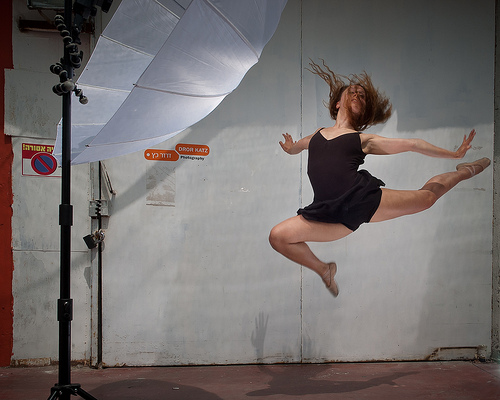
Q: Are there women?
A: Yes, there is a woman.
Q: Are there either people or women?
A: Yes, there is a woman.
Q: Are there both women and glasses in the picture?
A: No, there is a woman but no glasses.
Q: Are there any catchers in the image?
A: No, there are no catchers.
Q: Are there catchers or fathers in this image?
A: No, there are no catchers or fathers.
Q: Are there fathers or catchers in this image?
A: No, there are no catchers or fathers.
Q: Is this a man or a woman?
A: This is a woman.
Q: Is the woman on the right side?
A: Yes, the woman is on the right of the image.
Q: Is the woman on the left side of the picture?
A: No, the woman is on the right of the image.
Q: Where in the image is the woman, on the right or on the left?
A: The woman is on the right of the image.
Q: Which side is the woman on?
A: The woman is on the right of the image.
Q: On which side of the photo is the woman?
A: The woman is on the right of the image.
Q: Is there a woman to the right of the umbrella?
A: Yes, there is a woman to the right of the umbrella.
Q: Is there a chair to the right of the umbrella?
A: No, there is a woman to the right of the umbrella.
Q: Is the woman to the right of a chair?
A: No, the woman is to the right of the umbrella.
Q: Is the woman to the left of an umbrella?
A: No, the woman is to the right of an umbrella.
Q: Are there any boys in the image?
A: No, there are no boys.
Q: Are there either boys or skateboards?
A: No, there are no boys or skateboards.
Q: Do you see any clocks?
A: No, there are no clocks.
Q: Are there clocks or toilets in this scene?
A: No, there are no clocks or toilets.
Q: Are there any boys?
A: No, there are no boys.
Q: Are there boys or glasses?
A: No, there are no boys or glasses.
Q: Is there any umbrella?
A: Yes, there is an umbrella.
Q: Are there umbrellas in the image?
A: Yes, there is an umbrella.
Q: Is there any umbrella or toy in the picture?
A: Yes, there is an umbrella.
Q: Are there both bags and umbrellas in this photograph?
A: No, there is an umbrella but no bags.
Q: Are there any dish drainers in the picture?
A: No, there are no dish drainers.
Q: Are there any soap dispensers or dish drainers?
A: No, there are no dish drainers or soap dispensers.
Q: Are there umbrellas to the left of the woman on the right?
A: Yes, there is an umbrella to the left of the woman.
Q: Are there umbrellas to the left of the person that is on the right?
A: Yes, there is an umbrella to the left of the woman.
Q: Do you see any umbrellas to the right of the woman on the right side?
A: No, the umbrella is to the left of the woman.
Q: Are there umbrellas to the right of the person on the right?
A: No, the umbrella is to the left of the woman.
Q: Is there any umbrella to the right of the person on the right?
A: No, the umbrella is to the left of the woman.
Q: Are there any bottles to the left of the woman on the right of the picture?
A: No, there is an umbrella to the left of the woman.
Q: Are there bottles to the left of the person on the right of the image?
A: No, there is an umbrella to the left of the woman.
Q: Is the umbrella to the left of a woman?
A: Yes, the umbrella is to the left of a woman.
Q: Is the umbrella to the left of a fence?
A: No, the umbrella is to the left of a woman.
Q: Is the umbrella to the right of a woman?
A: No, the umbrella is to the left of a woman.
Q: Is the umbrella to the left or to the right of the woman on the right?
A: The umbrella is to the left of the woman.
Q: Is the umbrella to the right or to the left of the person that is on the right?
A: The umbrella is to the left of the woman.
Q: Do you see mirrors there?
A: No, there are no mirrors.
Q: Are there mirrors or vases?
A: No, there are no mirrors or vases.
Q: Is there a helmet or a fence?
A: No, there are no fences or helmets.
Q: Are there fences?
A: No, there are no fences.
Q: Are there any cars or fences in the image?
A: No, there are no fences or cars.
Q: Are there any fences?
A: No, there are no fences.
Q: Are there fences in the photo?
A: No, there are no fences.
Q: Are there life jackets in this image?
A: No, there are no life jackets.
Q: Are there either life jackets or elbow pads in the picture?
A: No, there are no life jackets or elbow pads.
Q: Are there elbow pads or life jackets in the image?
A: No, there are no life jackets or elbow pads.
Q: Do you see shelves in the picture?
A: No, there are no shelves.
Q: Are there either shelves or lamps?
A: No, there are no shelves or lamps.